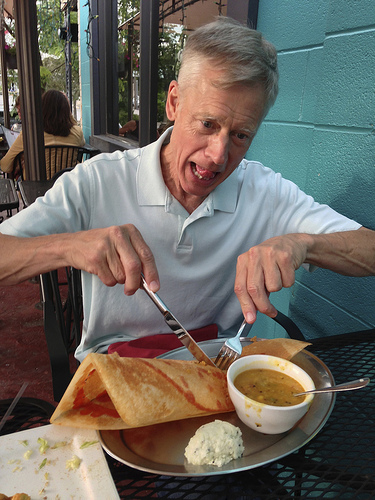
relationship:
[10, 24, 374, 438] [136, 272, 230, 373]
man holding knife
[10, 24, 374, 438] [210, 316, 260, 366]
man holding fork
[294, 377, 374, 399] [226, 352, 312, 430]
silverware in cup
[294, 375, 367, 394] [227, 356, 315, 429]
utensil in bowl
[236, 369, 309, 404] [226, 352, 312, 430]
soup inside cup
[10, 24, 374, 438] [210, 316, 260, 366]
person has fork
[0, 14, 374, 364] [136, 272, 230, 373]
man has knife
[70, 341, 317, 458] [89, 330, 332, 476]
food on plate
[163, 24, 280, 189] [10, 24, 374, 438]
head of a man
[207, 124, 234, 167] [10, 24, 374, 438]
nose of a man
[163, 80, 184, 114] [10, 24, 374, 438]
ear of a man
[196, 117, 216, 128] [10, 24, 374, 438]
eye of a man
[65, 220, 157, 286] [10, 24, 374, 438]
hand of a man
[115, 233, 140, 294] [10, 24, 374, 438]
finger of a man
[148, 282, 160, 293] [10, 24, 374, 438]
nail of a man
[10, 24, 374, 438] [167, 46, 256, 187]
man making a face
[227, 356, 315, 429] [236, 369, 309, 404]
bowl of soup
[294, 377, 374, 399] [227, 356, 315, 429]
spoon in bowl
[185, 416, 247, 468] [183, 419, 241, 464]
lump of potato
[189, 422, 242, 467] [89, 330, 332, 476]
salad on a platter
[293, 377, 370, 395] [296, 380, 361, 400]
handle of a spoon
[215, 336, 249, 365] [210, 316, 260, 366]
bottom of a fork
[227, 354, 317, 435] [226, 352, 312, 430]
bowl of soup